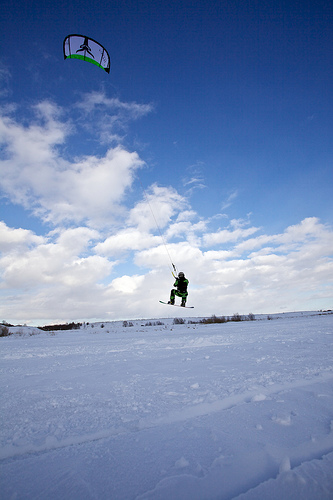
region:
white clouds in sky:
[235, 246, 259, 279]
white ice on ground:
[204, 421, 220, 446]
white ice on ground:
[230, 454, 253, 481]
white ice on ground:
[258, 472, 282, 487]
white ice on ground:
[93, 443, 111, 458]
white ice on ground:
[79, 428, 106, 457]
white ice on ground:
[56, 406, 90, 443]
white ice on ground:
[128, 418, 169, 443]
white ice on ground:
[185, 430, 217, 446]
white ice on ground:
[244, 405, 265, 424]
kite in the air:
[56, 28, 124, 76]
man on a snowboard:
[158, 268, 200, 312]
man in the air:
[162, 261, 198, 312]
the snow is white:
[59, 360, 190, 450]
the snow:
[63, 346, 185, 432]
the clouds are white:
[37, 242, 112, 291]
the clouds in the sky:
[23, 237, 105, 301]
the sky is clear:
[248, 178, 306, 219]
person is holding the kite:
[160, 263, 199, 309]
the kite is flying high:
[58, 33, 120, 78]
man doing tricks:
[151, 256, 193, 310]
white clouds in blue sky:
[21, 57, 83, 106]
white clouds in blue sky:
[46, 153, 77, 192]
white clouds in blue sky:
[92, 233, 132, 269]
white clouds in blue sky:
[19, 198, 69, 259]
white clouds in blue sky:
[198, 191, 269, 242]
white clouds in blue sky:
[122, 10, 180, 90]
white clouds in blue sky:
[195, 69, 257, 133]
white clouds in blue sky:
[115, 109, 174, 163]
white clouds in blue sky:
[212, 139, 278, 197]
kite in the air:
[34, 28, 135, 76]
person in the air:
[150, 257, 208, 320]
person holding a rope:
[132, 209, 198, 313]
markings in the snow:
[87, 363, 328, 492]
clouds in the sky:
[34, 128, 239, 266]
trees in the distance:
[36, 310, 282, 325]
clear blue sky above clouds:
[212, 141, 325, 210]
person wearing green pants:
[169, 293, 190, 302]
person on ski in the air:
[154, 300, 202, 315]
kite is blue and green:
[50, 34, 124, 70]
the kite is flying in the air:
[47, 34, 132, 87]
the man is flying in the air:
[154, 258, 220, 321]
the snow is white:
[5, 320, 331, 498]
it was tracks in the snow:
[68, 341, 308, 498]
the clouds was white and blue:
[17, 194, 161, 313]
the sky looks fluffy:
[22, 227, 171, 319]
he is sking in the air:
[152, 256, 229, 316]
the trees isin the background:
[43, 313, 85, 332]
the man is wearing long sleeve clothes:
[82, 253, 321, 316]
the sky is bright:
[1, 193, 66, 264]